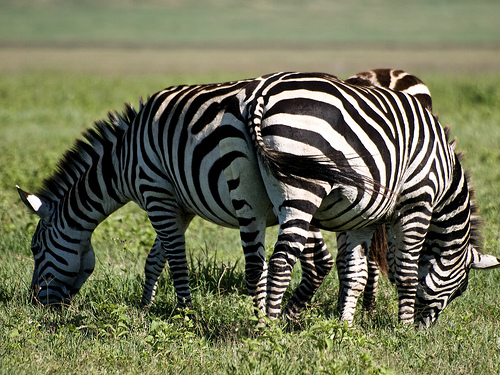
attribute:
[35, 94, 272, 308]
zebra — striped, white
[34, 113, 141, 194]
mane — black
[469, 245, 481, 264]
stripes — white, black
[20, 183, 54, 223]
ear — white, black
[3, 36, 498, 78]
road — dirt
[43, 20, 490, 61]
grass — green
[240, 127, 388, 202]
tail — black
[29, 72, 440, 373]
zebra — black, white, bent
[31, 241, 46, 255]
eye — black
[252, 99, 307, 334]
leg — back leg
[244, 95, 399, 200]
tail — in motion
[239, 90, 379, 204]
tail — black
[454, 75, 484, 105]
bush — green, small